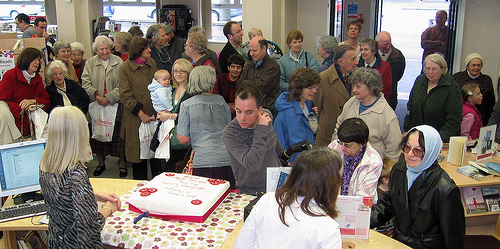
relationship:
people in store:
[3, 2, 495, 223] [3, 5, 484, 244]